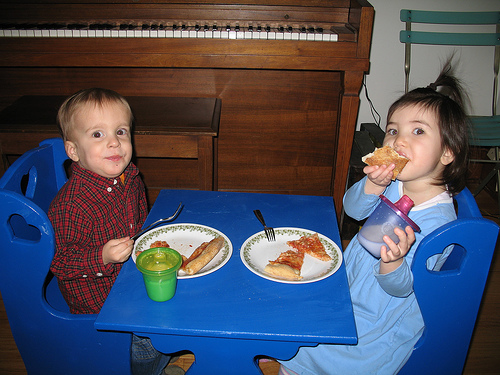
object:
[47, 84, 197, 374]
boy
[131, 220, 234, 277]
lunch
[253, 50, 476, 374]
girl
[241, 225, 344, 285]
lunch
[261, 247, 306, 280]
pizza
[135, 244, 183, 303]
spillproofcup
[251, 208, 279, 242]
fork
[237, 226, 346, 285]
plate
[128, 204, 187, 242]
fork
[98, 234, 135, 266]
boyshand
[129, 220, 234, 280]
plates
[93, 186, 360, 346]
table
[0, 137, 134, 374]
chair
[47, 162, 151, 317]
shirtflannel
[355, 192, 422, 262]
sipycup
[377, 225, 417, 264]
grilshand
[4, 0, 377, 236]
piano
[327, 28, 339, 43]
pianokeys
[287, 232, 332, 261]
pizzas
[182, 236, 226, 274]
hotdog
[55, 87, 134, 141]
hair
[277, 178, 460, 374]
blue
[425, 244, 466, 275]
heart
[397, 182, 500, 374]
childrenchair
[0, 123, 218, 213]
bench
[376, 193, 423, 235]
lid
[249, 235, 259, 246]
decoration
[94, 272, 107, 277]
buttons